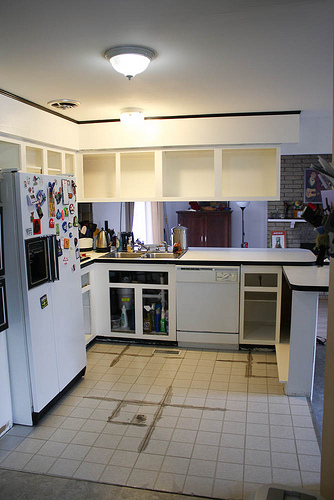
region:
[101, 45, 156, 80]
a ceiling light fixture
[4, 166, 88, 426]
part of a white refrigerator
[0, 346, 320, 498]
a white tile floor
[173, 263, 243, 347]
a white dishwasher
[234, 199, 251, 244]
part of a floor lamp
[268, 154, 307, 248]
part of a fireplace brick wall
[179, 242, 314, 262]
a white kitchen counter top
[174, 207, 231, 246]
part of a brown cabinet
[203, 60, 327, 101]
part of a white ceiling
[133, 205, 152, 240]
part of a window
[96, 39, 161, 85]
Light fixture on the ceiling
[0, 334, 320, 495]
White tiles are on the floor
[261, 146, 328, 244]
Bricks are on the wall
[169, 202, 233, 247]
A brown wooden cabinet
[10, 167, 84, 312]
Many magnets on the fridge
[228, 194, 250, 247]
A lamp is tall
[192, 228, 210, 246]
Two handles of a cabinet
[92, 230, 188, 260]
A silver double sink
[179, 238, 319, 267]
A countertop is empty and white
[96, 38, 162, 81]
The light is turned on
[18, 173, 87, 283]
Many colorful maginets on a fridge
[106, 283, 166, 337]
Cleaning products under a cabinet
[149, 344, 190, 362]
Small white air vent in the floor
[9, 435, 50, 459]
Small white floor tile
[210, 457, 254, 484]
Small white floor tile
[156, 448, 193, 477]
Small white floor tile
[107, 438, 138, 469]
Small white floor tile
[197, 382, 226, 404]
Small white floor tile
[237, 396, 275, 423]
Small white floor tile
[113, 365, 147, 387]
Small white floor tile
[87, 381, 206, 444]
Floor tiles with lines of wet mess between them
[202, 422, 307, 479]
Clean square white floor tiles in a kitchen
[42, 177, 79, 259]
Colorful kitchen magnets covering a white fridge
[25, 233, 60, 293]
Drink pouring station colored black on the door of a fridge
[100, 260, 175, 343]
White drawers with the doors removed and bottles visible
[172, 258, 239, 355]
White appliance door with an adjustable dial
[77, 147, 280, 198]
Tall white cabinets that are empty and brightly lit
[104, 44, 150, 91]
Round brass colored light fixture with a yellow shining bulb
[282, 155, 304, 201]
Gray colored brick wall with black lines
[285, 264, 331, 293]
White counter top with a black side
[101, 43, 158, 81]
ceiling fixture with bright light bulb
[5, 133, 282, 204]
white square open kitchen shelves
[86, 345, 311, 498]
kitchen floor tiles with repairs in grout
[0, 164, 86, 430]
large white refrigerator covered in magnets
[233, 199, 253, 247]
inexpensive standing light fixture with black base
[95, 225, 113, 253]
metal tea kettle on countertop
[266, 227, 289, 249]
red and white artwork poster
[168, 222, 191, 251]
shiny metal canister with round knob on lid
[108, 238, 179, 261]
chrome-colored stainless steel kitchen sink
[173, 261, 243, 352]
white dishwasher with simple knobs